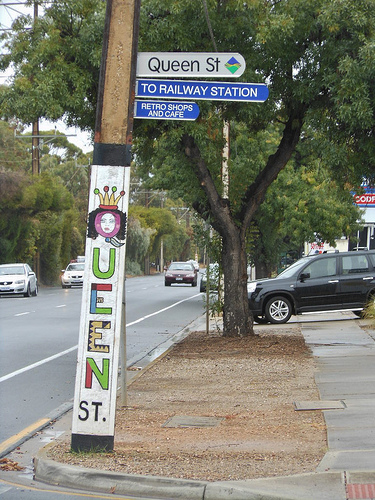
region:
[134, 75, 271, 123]
two blue and white street signs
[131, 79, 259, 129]
white lettering on blue background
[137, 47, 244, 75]
white sign with black lettering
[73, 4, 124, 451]
pole with three signs attached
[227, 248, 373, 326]
black suv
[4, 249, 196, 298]
three cars drving up the road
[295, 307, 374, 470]
sidewalk beside sign post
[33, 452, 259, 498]
gray curb of sidewalk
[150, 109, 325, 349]
trees planted on sidewalk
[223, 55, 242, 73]
green and blue diamond shape on white sign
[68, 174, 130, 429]
White sign with colorful design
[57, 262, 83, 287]
White car with headlights on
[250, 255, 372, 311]
Black SUV preparing to pull onto street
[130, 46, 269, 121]
Three signs on a pole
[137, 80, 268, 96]
Blue sign with words "to railway station"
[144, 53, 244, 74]
White sign with words "Queen St."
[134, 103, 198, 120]
Blue sign with words "retro shops and cafe"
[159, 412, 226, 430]
Concrete square in light brown dirt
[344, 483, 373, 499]
Red brick pathway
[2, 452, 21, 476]
Dead brown leaves at side of road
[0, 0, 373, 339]
large tree growing in gravel on sidewalk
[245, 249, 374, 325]
shiny black SUV pulling out of driveway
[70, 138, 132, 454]
tall vertical painted sign for Queen St.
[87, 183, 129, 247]
painted picture of a queen with black hair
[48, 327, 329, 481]
gravel area between sidewalk and street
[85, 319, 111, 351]
yellow and black letter E with stripes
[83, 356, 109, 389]
letter N painted half pink and green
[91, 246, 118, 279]
letter U painted solid green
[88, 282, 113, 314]
letter E painted red, blue, and green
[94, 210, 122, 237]
letter Q painted purple with a face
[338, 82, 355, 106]
Bright green leaves on tree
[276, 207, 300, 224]
Bright green leaves on tree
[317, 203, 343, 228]
Bright green leaves on tree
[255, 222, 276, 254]
Bright green leaves on tree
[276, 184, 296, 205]
Bright green leaves on tree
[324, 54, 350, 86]
Bright green leaves on tree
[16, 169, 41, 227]
Bright green leaves on tree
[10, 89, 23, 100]
Bright green leaves on tree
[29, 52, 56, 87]
Bright green leaves on tree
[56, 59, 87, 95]
Bright green leaves on tree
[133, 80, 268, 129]
blue and white street signs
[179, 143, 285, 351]
a large tree next to a road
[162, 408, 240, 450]
a metal access panel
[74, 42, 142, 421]
a painting on a post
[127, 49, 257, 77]
a and black street sign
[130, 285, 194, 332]
white line painted on a road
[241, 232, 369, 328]
a black vehicle on a side walk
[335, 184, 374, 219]
red, white and blue sign on a building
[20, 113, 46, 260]
a wood electrical pole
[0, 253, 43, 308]
a white car on the road